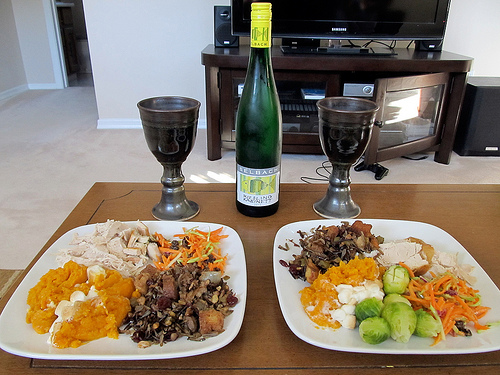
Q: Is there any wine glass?
A: Yes, there is a wine glass.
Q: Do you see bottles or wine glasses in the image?
A: Yes, there is a wine glass.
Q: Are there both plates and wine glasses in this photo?
A: Yes, there are both a wine glass and a plate.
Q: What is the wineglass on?
A: The wineglass is on the table.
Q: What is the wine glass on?
A: The wineglass is on the table.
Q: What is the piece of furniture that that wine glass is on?
A: The piece of furniture is a table.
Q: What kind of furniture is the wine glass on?
A: The wine glass is on the table.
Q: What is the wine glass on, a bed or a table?
A: The wine glass is on a table.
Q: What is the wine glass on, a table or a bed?
A: The wine glass is on a table.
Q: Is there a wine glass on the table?
A: Yes, there is a wine glass on the table.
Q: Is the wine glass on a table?
A: Yes, the wine glass is on a table.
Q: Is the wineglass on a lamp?
A: No, the wineglass is on a table.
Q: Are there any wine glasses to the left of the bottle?
A: Yes, there is a wine glass to the left of the bottle.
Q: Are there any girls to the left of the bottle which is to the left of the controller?
A: No, there is a wine glass to the left of the bottle.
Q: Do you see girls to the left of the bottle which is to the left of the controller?
A: No, there is a wine glass to the left of the bottle.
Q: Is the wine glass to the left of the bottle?
A: Yes, the wine glass is to the left of the bottle.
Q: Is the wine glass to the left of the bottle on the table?
A: Yes, the wine glass is to the left of the bottle.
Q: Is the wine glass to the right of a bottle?
A: No, the wine glass is to the left of a bottle.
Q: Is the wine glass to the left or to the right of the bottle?
A: The wine glass is to the left of the bottle.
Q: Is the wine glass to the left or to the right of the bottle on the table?
A: The wine glass is to the left of the bottle.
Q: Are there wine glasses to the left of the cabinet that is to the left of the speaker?
A: Yes, there is a wine glass to the left of the cabinet.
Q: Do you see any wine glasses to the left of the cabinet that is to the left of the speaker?
A: Yes, there is a wine glass to the left of the cabinet.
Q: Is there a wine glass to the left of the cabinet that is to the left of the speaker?
A: Yes, there is a wine glass to the left of the cabinet.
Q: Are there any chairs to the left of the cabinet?
A: No, there is a wine glass to the left of the cabinet.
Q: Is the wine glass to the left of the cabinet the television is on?
A: Yes, the wine glass is to the left of the cabinet.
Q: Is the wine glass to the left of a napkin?
A: No, the wine glass is to the left of the cabinet.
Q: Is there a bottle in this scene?
A: Yes, there is a bottle.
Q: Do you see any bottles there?
A: Yes, there is a bottle.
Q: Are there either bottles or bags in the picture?
A: Yes, there is a bottle.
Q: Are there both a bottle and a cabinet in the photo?
A: Yes, there are both a bottle and a cabinet.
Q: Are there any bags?
A: No, there are no bags.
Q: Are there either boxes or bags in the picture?
A: No, there are no bags or boxes.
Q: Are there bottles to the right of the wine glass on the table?
A: Yes, there is a bottle to the right of the wine glass.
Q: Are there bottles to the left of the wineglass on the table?
A: No, the bottle is to the right of the wine glass.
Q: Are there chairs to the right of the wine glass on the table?
A: No, there is a bottle to the right of the wine glass.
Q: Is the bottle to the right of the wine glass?
A: Yes, the bottle is to the right of the wine glass.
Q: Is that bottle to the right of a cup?
A: No, the bottle is to the right of the wine glass.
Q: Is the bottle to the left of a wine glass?
A: No, the bottle is to the right of a wine glass.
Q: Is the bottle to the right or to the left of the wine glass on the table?
A: The bottle is to the right of the wine glass.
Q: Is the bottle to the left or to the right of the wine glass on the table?
A: The bottle is to the right of the wine glass.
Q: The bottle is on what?
A: The bottle is on the table.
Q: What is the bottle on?
A: The bottle is on the table.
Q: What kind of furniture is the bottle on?
A: The bottle is on the table.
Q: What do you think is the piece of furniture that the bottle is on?
A: The piece of furniture is a table.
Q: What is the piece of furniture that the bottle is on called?
A: The piece of furniture is a table.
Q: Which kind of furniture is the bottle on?
A: The bottle is on the table.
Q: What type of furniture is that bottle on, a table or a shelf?
A: The bottle is on a table.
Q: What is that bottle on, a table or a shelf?
A: The bottle is on a table.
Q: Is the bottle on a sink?
A: No, the bottle is on a table.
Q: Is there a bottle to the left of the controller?
A: Yes, there is a bottle to the left of the controller.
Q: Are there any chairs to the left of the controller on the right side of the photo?
A: No, there is a bottle to the left of the controller.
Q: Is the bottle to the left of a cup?
A: No, the bottle is to the left of the controller.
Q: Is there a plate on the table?
A: Yes, there are plates on the table.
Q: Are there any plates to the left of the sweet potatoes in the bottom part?
A: Yes, there are plates to the left of the sweet potatoes.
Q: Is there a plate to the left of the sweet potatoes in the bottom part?
A: Yes, there are plates to the left of the sweet potatoes.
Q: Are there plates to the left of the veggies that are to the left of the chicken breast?
A: Yes, there are plates to the left of the sweet potatoes.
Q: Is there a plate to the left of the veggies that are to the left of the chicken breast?
A: Yes, there are plates to the left of the sweet potatoes.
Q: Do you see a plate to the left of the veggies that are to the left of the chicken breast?
A: Yes, there are plates to the left of the sweet potatoes.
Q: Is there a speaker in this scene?
A: Yes, there is a speaker.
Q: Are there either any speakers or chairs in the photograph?
A: Yes, there is a speaker.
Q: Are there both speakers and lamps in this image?
A: No, there is a speaker but no lamps.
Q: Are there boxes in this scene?
A: No, there are no boxes.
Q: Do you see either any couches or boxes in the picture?
A: No, there are no boxes or couches.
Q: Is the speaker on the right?
A: Yes, the speaker is on the right of the image.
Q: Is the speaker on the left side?
A: No, the speaker is on the right of the image.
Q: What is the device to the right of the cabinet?
A: The device is a speaker.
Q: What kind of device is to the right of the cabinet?
A: The device is a speaker.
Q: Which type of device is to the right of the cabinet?
A: The device is a speaker.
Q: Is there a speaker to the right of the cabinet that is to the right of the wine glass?
A: Yes, there is a speaker to the right of the cabinet.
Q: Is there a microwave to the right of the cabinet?
A: No, there is a speaker to the right of the cabinet.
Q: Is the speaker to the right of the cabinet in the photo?
A: Yes, the speaker is to the right of the cabinet.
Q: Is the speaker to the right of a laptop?
A: No, the speaker is to the right of the cabinet.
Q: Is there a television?
A: Yes, there is a television.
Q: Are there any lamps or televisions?
A: Yes, there is a television.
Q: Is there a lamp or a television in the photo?
A: Yes, there is a television.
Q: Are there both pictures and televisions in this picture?
A: No, there is a television but no pictures.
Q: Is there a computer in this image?
A: No, there are no computers.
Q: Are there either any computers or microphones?
A: No, there are no computers or microphones.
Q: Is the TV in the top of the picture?
A: Yes, the TV is in the top of the image.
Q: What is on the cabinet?
A: The television is on the cabinet.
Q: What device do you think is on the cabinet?
A: The device is a television.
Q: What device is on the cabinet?
A: The device is a television.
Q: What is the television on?
A: The television is on the cabinet.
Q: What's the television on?
A: The television is on the cabinet.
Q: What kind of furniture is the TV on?
A: The TV is on the cabinet.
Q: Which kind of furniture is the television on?
A: The TV is on the cabinet.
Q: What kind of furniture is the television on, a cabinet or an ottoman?
A: The television is on a cabinet.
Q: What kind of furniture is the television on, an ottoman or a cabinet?
A: The television is on a cabinet.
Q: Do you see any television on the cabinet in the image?
A: Yes, there is a television on the cabinet.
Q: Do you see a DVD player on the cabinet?
A: No, there is a television on the cabinet.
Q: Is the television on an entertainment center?
A: No, the television is on a cabinet.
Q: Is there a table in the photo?
A: Yes, there is a table.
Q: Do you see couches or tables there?
A: Yes, there is a table.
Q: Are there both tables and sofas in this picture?
A: No, there is a table but no sofas.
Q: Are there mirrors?
A: No, there are no mirrors.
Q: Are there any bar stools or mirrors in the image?
A: No, there are no mirrors or bar stools.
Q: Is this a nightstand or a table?
A: This is a table.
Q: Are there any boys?
A: No, there are no boys.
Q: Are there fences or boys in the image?
A: No, there are no boys or fences.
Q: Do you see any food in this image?
A: Yes, there is food.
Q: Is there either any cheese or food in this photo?
A: Yes, there is food.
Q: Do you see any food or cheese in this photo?
A: Yes, there is food.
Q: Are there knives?
A: No, there are no knives.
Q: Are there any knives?
A: No, there are no knives.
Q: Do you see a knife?
A: No, there are no knives.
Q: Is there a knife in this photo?
A: No, there are no knives.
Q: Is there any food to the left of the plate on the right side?
A: Yes, there is food to the left of the plate.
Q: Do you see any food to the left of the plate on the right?
A: Yes, there is food to the left of the plate.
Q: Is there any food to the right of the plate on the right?
A: No, the food is to the left of the plate.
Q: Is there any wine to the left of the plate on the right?
A: No, there is food to the left of the plate.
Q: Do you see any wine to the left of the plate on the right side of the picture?
A: No, there is food to the left of the plate.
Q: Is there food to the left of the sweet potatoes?
A: Yes, there is food to the left of the sweet potatoes.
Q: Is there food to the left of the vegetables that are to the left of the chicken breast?
A: Yes, there is food to the left of the sweet potatoes.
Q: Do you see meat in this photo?
A: Yes, there is meat.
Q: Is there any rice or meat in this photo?
A: Yes, there is meat.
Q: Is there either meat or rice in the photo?
A: Yes, there is meat.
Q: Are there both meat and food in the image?
A: Yes, there are both meat and food.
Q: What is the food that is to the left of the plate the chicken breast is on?
A: The food is meat.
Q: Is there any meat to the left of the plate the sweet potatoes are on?
A: Yes, there is meat to the left of the plate.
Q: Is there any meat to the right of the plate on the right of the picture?
A: No, the meat is to the left of the plate.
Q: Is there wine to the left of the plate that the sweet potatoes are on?
A: No, there is meat to the left of the plate.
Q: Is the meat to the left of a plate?
A: Yes, the meat is to the left of a plate.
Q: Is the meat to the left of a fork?
A: No, the meat is to the left of a plate.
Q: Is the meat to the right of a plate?
A: No, the meat is to the left of a plate.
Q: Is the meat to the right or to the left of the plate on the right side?
A: The meat is to the left of the plate.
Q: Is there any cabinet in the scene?
A: Yes, there is a cabinet.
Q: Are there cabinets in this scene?
A: Yes, there is a cabinet.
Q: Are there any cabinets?
A: Yes, there is a cabinet.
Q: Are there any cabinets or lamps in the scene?
A: Yes, there is a cabinet.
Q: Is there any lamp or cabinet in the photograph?
A: Yes, there is a cabinet.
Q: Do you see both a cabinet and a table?
A: Yes, there are both a cabinet and a table.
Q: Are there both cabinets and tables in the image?
A: Yes, there are both a cabinet and a table.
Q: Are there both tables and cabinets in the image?
A: Yes, there are both a cabinet and a table.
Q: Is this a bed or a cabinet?
A: This is a cabinet.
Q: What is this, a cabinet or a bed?
A: This is a cabinet.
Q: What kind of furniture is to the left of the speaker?
A: The piece of furniture is a cabinet.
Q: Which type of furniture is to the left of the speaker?
A: The piece of furniture is a cabinet.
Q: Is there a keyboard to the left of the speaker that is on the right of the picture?
A: No, there is a cabinet to the left of the speaker.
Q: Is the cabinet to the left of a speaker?
A: Yes, the cabinet is to the left of a speaker.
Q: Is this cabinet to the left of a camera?
A: No, the cabinet is to the left of a speaker.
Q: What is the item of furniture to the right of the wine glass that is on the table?
A: The piece of furniture is a cabinet.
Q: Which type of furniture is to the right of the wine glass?
A: The piece of furniture is a cabinet.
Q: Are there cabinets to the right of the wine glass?
A: Yes, there is a cabinet to the right of the wine glass.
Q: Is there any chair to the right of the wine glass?
A: No, there is a cabinet to the right of the wine glass.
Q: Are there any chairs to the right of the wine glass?
A: No, there is a cabinet to the right of the wine glass.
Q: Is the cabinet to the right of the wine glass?
A: Yes, the cabinet is to the right of the wine glass.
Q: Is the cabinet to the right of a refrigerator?
A: No, the cabinet is to the right of the wine glass.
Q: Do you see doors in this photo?
A: Yes, there is a door.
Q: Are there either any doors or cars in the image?
A: Yes, there is a door.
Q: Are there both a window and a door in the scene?
A: No, there is a door but no windows.